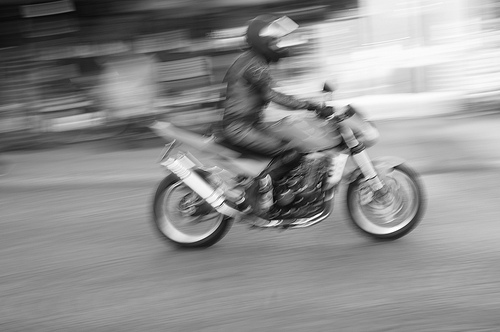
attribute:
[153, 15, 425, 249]
bike — fast, blurry, black, light, moving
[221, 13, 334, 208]
man — sitting, riding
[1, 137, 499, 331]
road — blurry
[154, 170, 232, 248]
wheel — round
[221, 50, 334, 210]
outfit — dark, leather